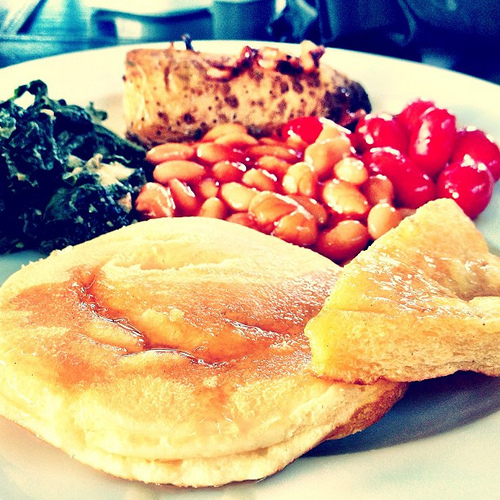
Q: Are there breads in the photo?
A: Yes, there is a bread.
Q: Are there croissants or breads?
A: Yes, there is a bread.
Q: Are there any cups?
A: No, there are no cups.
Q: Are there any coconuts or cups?
A: No, there are no cups or coconuts.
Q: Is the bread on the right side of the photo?
A: Yes, the bread is on the right of the image.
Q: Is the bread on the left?
A: No, the bread is on the right of the image.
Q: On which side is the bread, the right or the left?
A: The bread is on the right of the image.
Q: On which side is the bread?
A: The bread is on the right of the image.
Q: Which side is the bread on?
A: The bread is on the right of the image.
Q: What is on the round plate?
A: The bread is on the plate.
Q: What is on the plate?
A: The bread is on the plate.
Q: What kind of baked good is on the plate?
A: The food is a bread.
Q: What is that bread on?
A: The bread is on the plate.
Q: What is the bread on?
A: The bread is on the plate.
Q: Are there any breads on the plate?
A: Yes, there is a bread on the plate.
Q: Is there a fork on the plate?
A: No, there is a bread on the plate.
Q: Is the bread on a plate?
A: Yes, the bread is on a plate.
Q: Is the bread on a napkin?
A: No, the bread is on a plate.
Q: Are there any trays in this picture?
A: No, there are no trays.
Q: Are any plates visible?
A: Yes, there is a plate.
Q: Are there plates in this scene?
A: Yes, there is a plate.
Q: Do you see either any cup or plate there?
A: Yes, there is a plate.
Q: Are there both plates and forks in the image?
A: No, there is a plate but no forks.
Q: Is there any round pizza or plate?
A: Yes, there is a round plate.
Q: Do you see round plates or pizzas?
A: Yes, there is a round plate.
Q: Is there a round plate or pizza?
A: Yes, there is a round plate.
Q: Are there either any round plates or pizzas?
A: Yes, there is a round plate.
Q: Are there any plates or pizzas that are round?
A: Yes, the plate is round.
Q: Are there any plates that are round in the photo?
A: Yes, there is a round plate.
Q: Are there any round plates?
A: Yes, there is a round plate.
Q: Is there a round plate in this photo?
A: Yes, there is a round plate.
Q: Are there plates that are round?
A: Yes, there is a plate that is round.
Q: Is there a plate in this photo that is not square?
A: Yes, there is a round plate.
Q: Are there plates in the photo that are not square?
A: Yes, there is a round plate.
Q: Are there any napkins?
A: No, there are no napkins.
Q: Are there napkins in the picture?
A: No, there are no napkins.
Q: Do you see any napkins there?
A: No, there are no napkins.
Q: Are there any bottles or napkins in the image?
A: No, there are no napkins or bottles.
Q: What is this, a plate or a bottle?
A: This is a plate.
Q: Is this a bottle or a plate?
A: This is a plate.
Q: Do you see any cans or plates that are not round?
A: No, there is a plate but it is round.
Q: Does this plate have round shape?
A: Yes, the plate is round.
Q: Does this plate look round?
A: Yes, the plate is round.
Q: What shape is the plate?
A: The plate is round.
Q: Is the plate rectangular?
A: No, the plate is round.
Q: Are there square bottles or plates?
A: No, there is a plate but it is round.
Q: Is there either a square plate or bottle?
A: No, there is a plate but it is round.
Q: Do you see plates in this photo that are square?
A: No, there is a plate but it is round.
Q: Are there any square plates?
A: No, there is a plate but it is round.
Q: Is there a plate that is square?
A: No, there is a plate but it is round.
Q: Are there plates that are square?
A: No, there is a plate but it is round.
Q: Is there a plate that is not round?
A: No, there is a plate but it is round.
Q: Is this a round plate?
A: Yes, this is a round plate.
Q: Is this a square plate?
A: No, this is a round plate.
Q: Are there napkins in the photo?
A: No, there are no napkins.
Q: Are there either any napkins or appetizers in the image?
A: No, there are no napkins or appetizers.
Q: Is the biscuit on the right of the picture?
A: Yes, the biscuit is on the right of the image.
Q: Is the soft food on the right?
A: Yes, the biscuit is on the right of the image.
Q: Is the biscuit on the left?
A: No, the biscuit is on the right of the image.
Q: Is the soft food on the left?
A: No, the biscuit is on the right of the image.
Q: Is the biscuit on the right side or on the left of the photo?
A: The biscuit is on the right of the image.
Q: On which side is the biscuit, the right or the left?
A: The biscuit is on the right of the image.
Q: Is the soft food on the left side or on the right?
A: The biscuit is on the right of the image.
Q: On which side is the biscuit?
A: The biscuit is on the right of the image.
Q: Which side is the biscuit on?
A: The biscuit is on the right of the image.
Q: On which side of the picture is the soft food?
A: The biscuit is on the right of the image.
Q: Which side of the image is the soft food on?
A: The biscuit is on the right of the image.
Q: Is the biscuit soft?
A: Yes, the biscuit is soft.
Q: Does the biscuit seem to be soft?
A: Yes, the biscuit is soft.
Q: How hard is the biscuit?
A: The biscuit is soft.